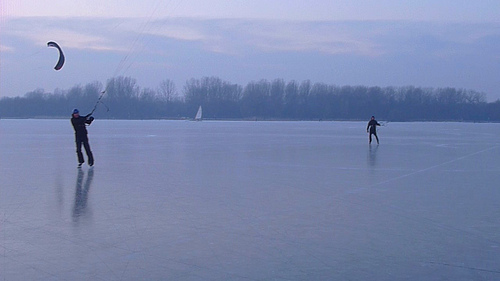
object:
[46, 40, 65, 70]
kite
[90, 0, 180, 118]
rope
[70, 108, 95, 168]
person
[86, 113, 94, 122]
hands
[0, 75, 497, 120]
trees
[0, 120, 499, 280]
lake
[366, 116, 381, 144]
person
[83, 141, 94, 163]
leg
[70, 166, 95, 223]
reflection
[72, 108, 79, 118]
head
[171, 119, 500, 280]
frozen lake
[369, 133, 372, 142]
leg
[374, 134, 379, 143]
leg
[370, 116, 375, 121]
head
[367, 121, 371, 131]
arm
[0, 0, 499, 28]
sky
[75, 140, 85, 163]
leg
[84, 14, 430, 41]
clouds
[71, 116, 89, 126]
arm